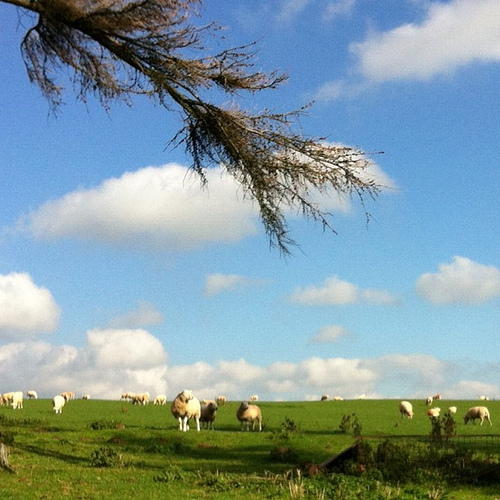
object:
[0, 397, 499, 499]
field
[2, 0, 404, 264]
leaves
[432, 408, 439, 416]
white fleece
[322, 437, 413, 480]
bushes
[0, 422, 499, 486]
shadow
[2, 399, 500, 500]
ground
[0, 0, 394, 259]
branch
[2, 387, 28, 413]
sheep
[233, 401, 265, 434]
sheep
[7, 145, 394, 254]
clouds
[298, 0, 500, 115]
clouds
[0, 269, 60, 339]
clouds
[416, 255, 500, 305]
clouds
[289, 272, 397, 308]
clouds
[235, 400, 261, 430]
sheep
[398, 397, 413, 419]
sheep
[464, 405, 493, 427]
sheep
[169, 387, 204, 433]
sheep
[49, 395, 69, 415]
sheep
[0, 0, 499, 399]
sky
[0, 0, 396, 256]
tree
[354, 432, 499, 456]
fence